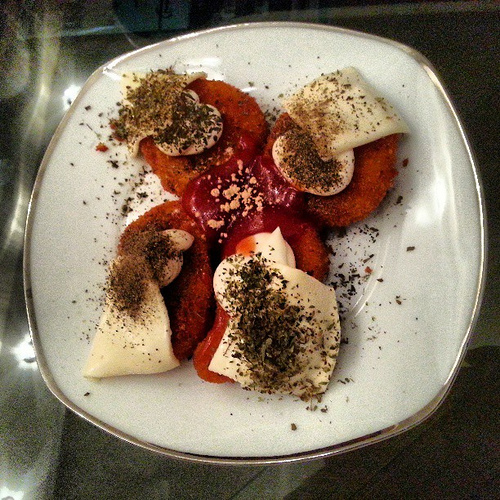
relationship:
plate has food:
[23, 20, 490, 469] [71, 43, 418, 427]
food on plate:
[71, 43, 418, 427] [23, 20, 490, 469]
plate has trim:
[23, 20, 490, 469] [24, 20, 488, 467]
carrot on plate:
[139, 77, 268, 198] [23, 20, 490, 469]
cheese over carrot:
[126, 70, 225, 158] [139, 77, 268, 198]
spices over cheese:
[113, 66, 224, 156] [126, 70, 225, 158]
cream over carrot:
[235, 226, 299, 270] [196, 214, 331, 386]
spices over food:
[78, 64, 402, 399] [71, 43, 418, 427]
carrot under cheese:
[139, 77, 268, 198] [126, 70, 225, 158]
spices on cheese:
[113, 66, 224, 156] [126, 70, 225, 158]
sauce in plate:
[183, 130, 305, 259] [23, 20, 490, 469]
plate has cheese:
[23, 20, 490, 469] [83, 64, 411, 396]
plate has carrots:
[23, 20, 490, 469] [118, 79, 398, 384]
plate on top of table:
[23, 20, 490, 469] [1, 1, 498, 497]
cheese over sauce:
[198, 158, 291, 244] [183, 130, 305, 259]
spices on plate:
[78, 64, 402, 399] [23, 20, 490, 469]